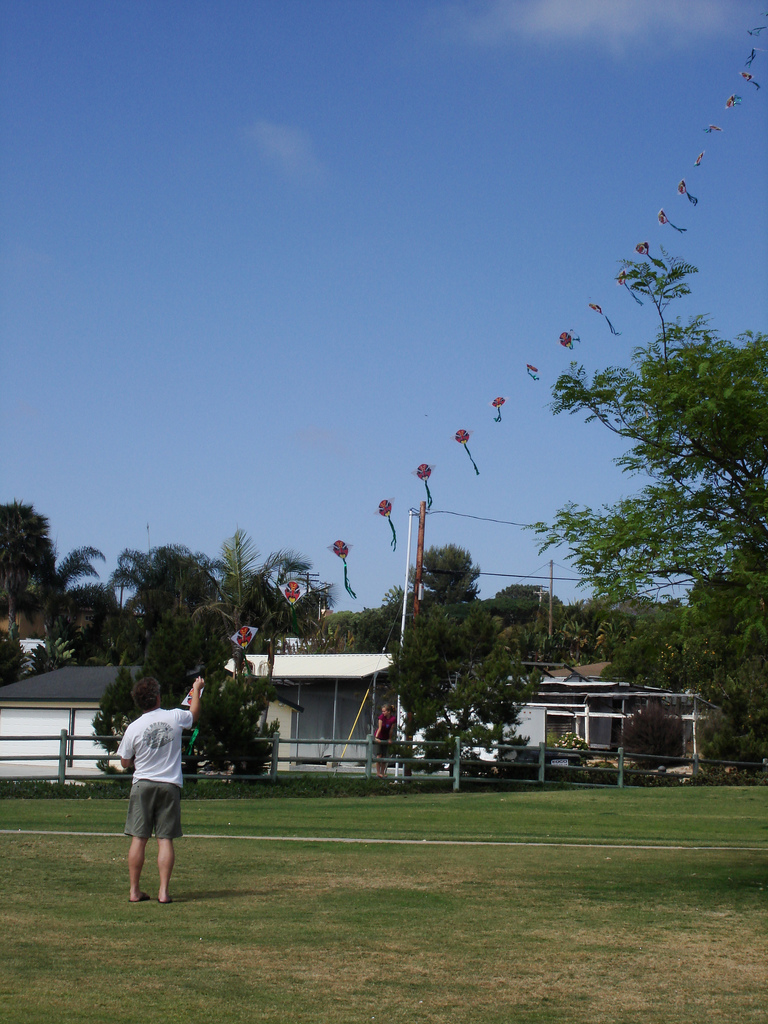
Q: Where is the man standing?
A: On a field.